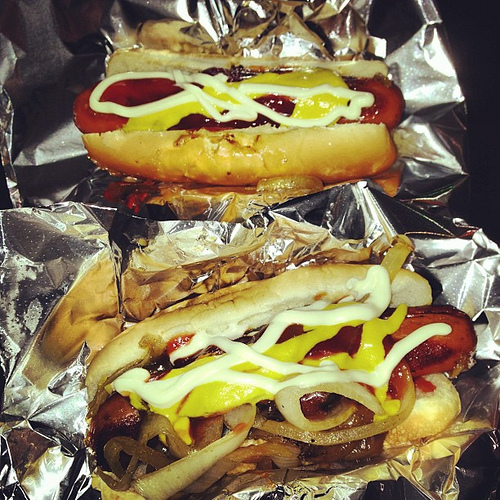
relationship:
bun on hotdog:
[84, 264, 477, 500] [88, 388, 153, 440]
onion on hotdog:
[252, 364, 415, 444] [76, 258, 477, 498]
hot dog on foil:
[85, 303, 477, 471] [3, 219, 499, 496]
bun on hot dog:
[84, 264, 477, 500] [83, 265, 477, 492]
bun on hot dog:
[84, 264, 477, 500] [84, 301, 481, 444]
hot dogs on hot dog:
[71, 73, 477, 474] [71, 46, 404, 186]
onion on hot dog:
[96, 375, 416, 493] [83, 265, 477, 492]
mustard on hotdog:
[126, 71, 351, 128] [66, 69, 415, 136]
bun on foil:
[67, 44, 412, 197] [3, 2, 487, 250]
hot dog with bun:
[85, 303, 477, 471] [84, 264, 477, 500]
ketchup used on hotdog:
[89, 68, 407, 450] [69, 43, 408, 188]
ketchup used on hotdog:
[274, 313, 367, 360] [76, 258, 477, 498]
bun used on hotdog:
[84, 264, 477, 500] [76, 258, 477, 498]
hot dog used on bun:
[58, 252, 461, 479] [84, 258, 492, 498]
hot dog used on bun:
[73, 75, 404, 134] [78, 48, 410, 191]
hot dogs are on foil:
[71, 73, 477, 474] [2, 1, 496, 499]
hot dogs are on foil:
[54, 6, 459, 499] [2, 1, 496, 499]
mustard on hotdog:
[118, 69, 407, 450] [76, 258, 477, 498]